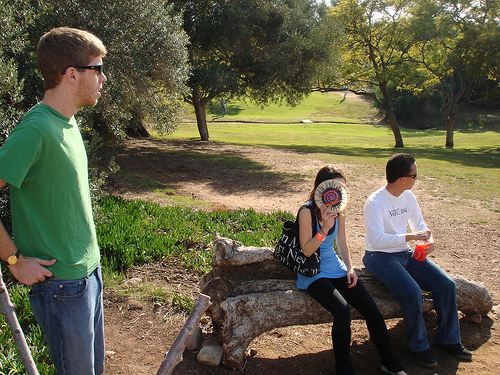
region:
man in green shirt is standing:
[1, 27, 111, 374]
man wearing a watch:
[2, 247, 24, 269]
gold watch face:
[6, 252, 18, 265]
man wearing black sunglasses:
[70, 62, 105, 75]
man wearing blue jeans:
[28, 265, 108, 374]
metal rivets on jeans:
[56, 285, 66, 289]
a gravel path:
[124, 132, 499, 302]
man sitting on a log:
[364, 155, 481, 368]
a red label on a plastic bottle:
[413, 233, 430, 264]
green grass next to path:
[93, 194, 302, 310]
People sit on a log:
[287, 141, 482, 374]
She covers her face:
[298, 154, 378, 373]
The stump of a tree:
[175, 234, 260, 374]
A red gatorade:
[413, 226, 433, 269]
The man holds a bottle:
[361, 139, 498, 359]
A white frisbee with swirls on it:
[305, 172, 352, 223]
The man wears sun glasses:
[23, 20, 118, 119]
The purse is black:
[265, 214, 330, 283]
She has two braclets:
[309, 219, 331, 251]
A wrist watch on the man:
[0, 243, 18, 276]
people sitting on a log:
[143, 65, 493, 357]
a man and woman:
[125, 134, 494, 331]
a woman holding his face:
[240, 143, 392, 373]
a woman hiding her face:
[215, 106, 397, 369]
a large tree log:
[135, 160, 472, 370]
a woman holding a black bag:
[265, 115, 400, 354]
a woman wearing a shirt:
[229, 115, 393, 374]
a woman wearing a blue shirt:
[252, 132, 429, 356]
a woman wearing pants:
[183, 110, 418, 372]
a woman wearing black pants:
[208, 141, 432, 343]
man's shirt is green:
[8, 101, 149, 310]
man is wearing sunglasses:
[57, 46, 115, 86]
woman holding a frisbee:
[296, 158, 368, 241]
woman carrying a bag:
[259, 215, 333, 286]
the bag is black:
[271, 214, 328, 291]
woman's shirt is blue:
[300, 196, 360, 285]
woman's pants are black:
[289, 268, 401, 373]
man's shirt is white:
[362, 192, 442, 253]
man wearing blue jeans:
[361, 241, 485, 358]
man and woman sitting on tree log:
[176, 132, 493, 346]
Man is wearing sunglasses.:
[1, 24, 127, 374]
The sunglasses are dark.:
[1, 20, 120, 341]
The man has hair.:
[1, 20, 140, 372]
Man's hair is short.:
[4, 20, 140, 373]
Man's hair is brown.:
[1, 25, 125, 374]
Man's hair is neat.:
[0, 21, 131, 373]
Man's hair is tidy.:
[0, 17, 132, 373]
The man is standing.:
[0, 17, 125, 372]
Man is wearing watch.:
[0, 24, 110, 316]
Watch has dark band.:
[0, 26, 125, 373]